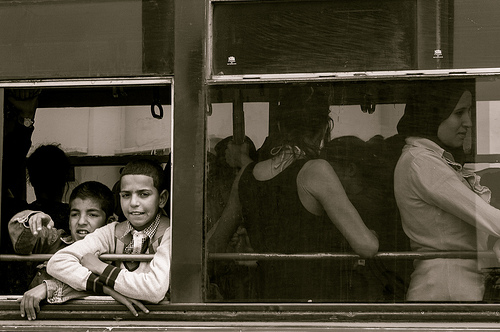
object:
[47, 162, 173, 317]
boy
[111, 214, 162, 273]
shirt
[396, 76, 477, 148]
black scarf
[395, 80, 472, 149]
head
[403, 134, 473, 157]
scarf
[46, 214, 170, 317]
young boy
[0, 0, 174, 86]
window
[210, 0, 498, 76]
window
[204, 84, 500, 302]
window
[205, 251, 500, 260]
rail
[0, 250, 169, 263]
rail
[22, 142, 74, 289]
people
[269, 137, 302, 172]
tie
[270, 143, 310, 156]
woman's neck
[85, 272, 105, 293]
stripes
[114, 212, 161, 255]
collar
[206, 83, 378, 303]
lady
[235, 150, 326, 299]
tank top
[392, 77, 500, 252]
lady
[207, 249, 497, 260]
steel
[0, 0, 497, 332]
bus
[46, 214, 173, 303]
sweater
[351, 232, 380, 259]
elbow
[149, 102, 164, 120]
strap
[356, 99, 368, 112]
strap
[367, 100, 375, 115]
strap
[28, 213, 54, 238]
hand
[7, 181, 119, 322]
boy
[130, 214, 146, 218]
lower lip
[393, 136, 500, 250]
blouse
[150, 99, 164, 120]
handle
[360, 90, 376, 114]
handle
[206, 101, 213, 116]
handle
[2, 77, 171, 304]
window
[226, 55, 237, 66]
logo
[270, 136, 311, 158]
neck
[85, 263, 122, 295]
cuff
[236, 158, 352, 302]
dress